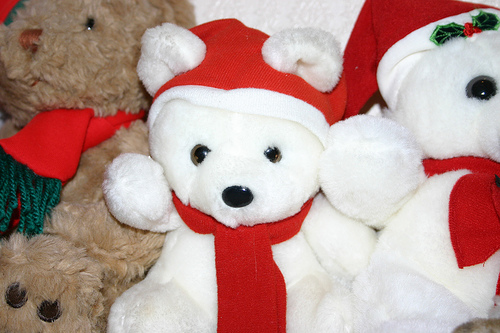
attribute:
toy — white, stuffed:
[120, 52, 328, 333]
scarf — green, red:
[4, 105, 103, 215]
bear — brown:
[7, 17, 153, 293]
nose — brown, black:
[16, 22, 42, 48]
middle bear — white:
[115, 33, 372, 331]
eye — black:
[454, 75, 500, 106]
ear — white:
[126, 21, 197, 83]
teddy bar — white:
[135, 13, 339, 315]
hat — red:
[167, 21, 324, 105]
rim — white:
[156, 94, 315, 121]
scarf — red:
[190, 215, 291, 327]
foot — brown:
[8, 249, 111, 321]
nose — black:
[223, 181, 253, 212]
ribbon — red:
[460, 22, 492, 41]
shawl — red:
[451, 152, 492, 244]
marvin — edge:
[16, 181, 50, 237]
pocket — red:
[293, 7, 367, 41]